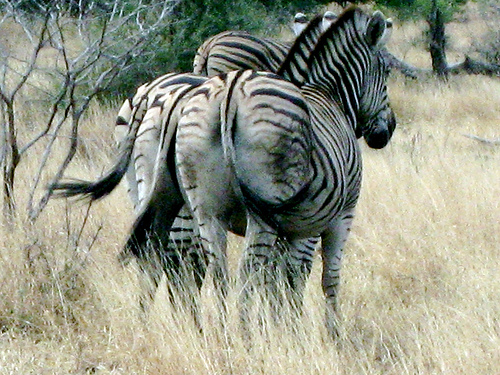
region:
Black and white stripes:
[246, 71, 304, 126]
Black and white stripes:
[315, 49, 350, 75]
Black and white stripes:
[337, 25, 405, 71]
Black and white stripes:
[336, 66, 411, 125]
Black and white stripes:
[310, 115, 357, 160]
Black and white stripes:
[302, 185, 378, 220]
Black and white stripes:
[240, 30, 277, 59]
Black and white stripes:
[212, 30, 243, 79]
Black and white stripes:
[163, 70, 203, 116]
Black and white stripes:
[260, 75, 350, 204]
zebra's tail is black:
[41, 139, 137, 229]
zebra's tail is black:
[232, 179, 340, 266]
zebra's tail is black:
[211, 146, 322, 257]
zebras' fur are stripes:
[109, 38, 366, 241]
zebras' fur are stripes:
[89, 29, 444, 347]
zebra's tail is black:
[229, 176, 298, 234]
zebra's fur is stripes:
[194, 8, 451, 268]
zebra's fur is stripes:
[186, 26, 360, 353]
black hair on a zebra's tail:
[222, 172, 324, 242]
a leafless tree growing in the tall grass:
[0, 0, 212, 309]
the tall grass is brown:
[13, 223, 473, 370]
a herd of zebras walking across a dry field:
[41, 9, 420, 339]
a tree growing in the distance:
[394, 2, 478, 77]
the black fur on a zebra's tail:
[47, 165, 126, 212]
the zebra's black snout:
[368, 103, 402, 158]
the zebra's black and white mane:
[303, 6, 370, 94]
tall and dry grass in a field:
[383, 137, 496, 329]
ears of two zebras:
[294, 8, 404, 40]